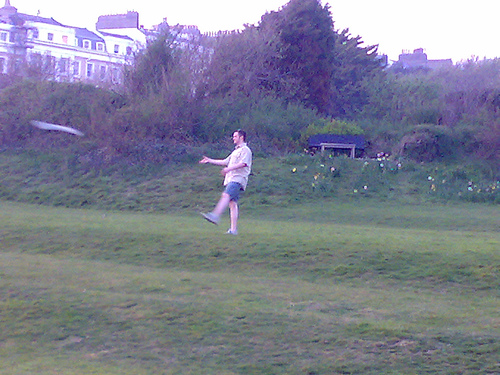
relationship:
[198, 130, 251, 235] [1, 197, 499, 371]
man on field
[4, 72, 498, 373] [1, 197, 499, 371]
grass on field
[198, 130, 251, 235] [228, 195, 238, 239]
man standing on leg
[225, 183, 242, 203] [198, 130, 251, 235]
shorts are on man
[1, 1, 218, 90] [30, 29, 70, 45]
building with windows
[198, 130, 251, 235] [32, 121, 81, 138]
man threw object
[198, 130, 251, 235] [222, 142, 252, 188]
man wearing shirt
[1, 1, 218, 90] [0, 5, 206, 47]
building has roof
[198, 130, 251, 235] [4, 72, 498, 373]
man on grass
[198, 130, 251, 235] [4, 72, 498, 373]
man on green grass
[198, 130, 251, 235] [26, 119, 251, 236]
man playing frisbee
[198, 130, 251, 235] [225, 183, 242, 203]
man wearing shorts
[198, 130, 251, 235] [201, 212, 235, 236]
man wearing shoes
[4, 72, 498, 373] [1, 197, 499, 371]
grass in a field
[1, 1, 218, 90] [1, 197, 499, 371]
building behind field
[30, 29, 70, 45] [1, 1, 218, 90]
windows on building